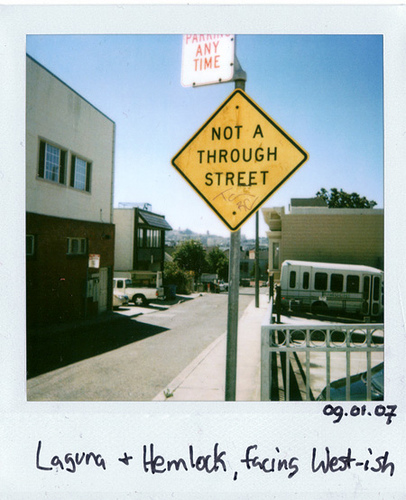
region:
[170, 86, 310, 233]
yellow sign with black lettering on a galvanized steel post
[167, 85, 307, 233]
yellow and black sign alerting people that it is not a thru street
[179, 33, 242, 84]
white sign with red lettering on galvanized steel post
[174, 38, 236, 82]
white sign with red lettering above the yellow sign with black lettering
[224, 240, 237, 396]
galvanized steel post holding yellow and black sign and red and white sign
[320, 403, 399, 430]
date written on the front of the picture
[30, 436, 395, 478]
writing on the front of the picture summarizing where the picture was taken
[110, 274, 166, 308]
white extended cab truck parked between two buildings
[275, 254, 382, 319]
white, school bus type bus parked beside white brick building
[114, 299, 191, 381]
road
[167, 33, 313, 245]
two road signs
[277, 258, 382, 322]
small white and green shuttle bus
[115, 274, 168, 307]
white pickup truck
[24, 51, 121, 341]
two story building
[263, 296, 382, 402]
white metal fence surrounding parking lot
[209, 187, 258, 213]
red graffiti on a street sign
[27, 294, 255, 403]
grey pavement of a street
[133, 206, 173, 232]
black awning overhang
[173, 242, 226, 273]
green leafy trees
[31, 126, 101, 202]
second story windows with black shutters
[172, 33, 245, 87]
White square sign with red letters.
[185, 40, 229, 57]
The word ANY in red letters.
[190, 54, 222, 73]
The word TIME in red letters.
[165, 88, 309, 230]
A diamond shaped sign.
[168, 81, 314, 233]
Yellow sign with black writing.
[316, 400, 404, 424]
The date 09.01.07 written on picture.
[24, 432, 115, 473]
The word Laguna written on picture.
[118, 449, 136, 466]
The & symbol written on picture.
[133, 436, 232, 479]
The word Hemlock written on picture.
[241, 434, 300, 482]
The word facing written on picture.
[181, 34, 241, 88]
part of a street sign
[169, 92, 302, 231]
a street sign with graffiti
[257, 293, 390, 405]
a railing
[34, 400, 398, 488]
description written on the photograph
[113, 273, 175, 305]
part of a white pickup truck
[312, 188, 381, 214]
the top of a tree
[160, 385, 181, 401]
a weed growing in the sidewalk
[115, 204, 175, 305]
a building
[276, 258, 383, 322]
a van in a paking lot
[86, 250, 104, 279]
a sign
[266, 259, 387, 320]
a small passenger bus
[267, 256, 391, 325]
white bus with green stripes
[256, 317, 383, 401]
a white metallic rail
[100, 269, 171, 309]
pick-up truck on the left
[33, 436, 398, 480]
a label for the photo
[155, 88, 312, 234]
caution sign with information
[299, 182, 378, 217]
tree peeking above building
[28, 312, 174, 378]
shadow on the street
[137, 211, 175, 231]
awning above the windows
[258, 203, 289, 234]
sign with a triangle